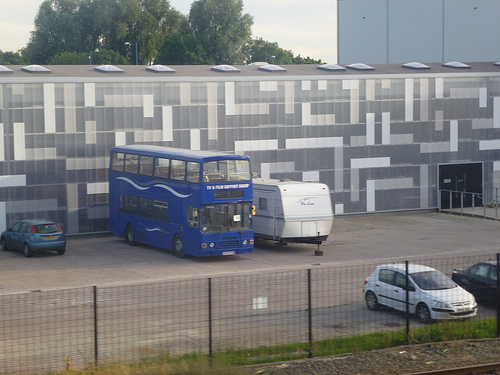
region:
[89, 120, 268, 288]
a blue double decker bus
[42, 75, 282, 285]
a blue bus parked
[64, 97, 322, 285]
a bus parked in lot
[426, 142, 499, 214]
a door to building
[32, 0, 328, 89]
trees behind the building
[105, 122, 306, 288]
a blue passenger bus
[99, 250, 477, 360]
a metal fence against grass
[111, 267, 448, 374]
a tall metal fence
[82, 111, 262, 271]
a tall blue bus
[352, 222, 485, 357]
a white vehicle parked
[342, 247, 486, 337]
the car is parked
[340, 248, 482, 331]
the car is white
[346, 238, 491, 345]
fence in front of the car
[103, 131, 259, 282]
a double-decker bus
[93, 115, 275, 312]
the bus is blue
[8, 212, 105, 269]
the car is blue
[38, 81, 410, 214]
the building has glass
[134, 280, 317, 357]
the fence is black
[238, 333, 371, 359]
the grass on the ground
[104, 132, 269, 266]
A double-decker bus is parked here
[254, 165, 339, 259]
This is a pull behind camper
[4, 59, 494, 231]
This is a building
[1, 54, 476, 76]
Skylights are on the roof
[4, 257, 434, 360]
A fence is here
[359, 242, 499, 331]
Cars are parked behind the fence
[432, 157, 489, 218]
The building's entrance way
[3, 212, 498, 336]
This is a parking lot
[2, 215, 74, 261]
This car is blue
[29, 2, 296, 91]
Trees are growing behind the building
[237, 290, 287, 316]
white square on road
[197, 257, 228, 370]
black post on the fence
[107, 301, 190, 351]
black link fence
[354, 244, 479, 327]
white car parked in spot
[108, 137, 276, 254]
blue double decker bus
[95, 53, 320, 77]
solar panels on the roof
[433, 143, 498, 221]
large cargo door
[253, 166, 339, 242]
white trailer parked on the side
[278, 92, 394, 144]
gray and white stone on building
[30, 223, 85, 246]
yellow license plate oncar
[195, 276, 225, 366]
Black bar on pole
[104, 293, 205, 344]
Grey wiring on gate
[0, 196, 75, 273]
Green car parked in lot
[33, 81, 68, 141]
White strip on wall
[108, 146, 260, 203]
Top half of double bus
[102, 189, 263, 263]
Bottom half of double bus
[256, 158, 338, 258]
White van parked in lot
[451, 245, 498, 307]
Black car parked in lot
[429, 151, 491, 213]
Black double doors on building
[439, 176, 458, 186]
White sign on door